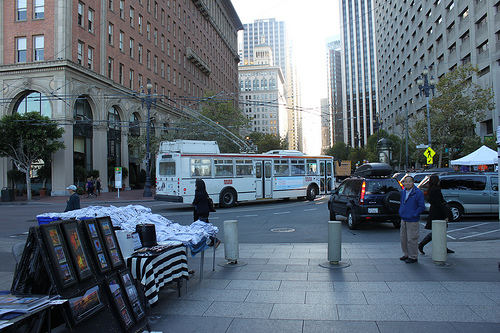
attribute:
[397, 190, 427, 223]
shirt — blue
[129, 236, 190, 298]
table cloth — black, white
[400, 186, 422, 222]
jacket — blue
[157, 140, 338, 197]
bus — white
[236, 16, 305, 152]
building — tall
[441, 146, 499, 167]
canopy — white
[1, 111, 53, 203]
tree — growing, medium size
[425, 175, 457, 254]
lady — walking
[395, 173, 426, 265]
man — asian, standing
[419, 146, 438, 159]
sign — yellow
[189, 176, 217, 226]
woman — standing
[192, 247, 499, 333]
sidewalk — paved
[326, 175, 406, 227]
suv — blue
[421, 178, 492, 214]
minivan — parked